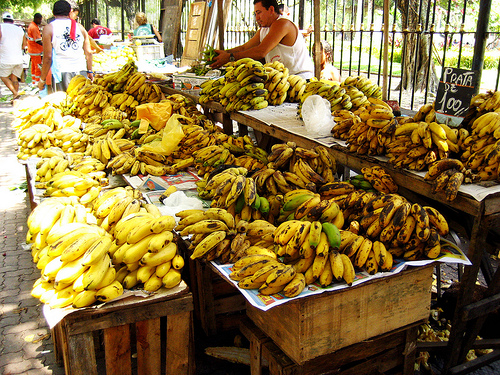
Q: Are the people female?
A: No, they are both male and female.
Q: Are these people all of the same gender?
A: No, they are both male and female.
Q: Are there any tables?
A: Yes, there is a table.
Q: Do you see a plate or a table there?
A: Yes, there is a table.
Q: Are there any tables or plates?
A: Yes, there is a table.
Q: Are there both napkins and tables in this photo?
A: No, there is a table but no napkins.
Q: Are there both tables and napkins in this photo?
A: No, there is a table but no napkins.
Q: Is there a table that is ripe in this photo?
A: Yes, there is a ripe table.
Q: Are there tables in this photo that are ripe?
A: Yes, there is a table that is ripe.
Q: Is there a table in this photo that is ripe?
A: Yes, there is a table that is ripe.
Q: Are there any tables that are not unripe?
A: Yes, there is an ripe table.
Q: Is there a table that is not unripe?
A: Yes, there is an ripe table.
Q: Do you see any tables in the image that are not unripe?
A: Yes, there is an ripe table.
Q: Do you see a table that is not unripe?
A: Yes, there is an ripe table.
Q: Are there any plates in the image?
A: No, there are no plates.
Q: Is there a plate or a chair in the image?
A: No, there are no plates or chairs.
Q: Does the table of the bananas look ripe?
A: Yes, the table is ripe.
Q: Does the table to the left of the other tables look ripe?
A: Yes, the table is ripe.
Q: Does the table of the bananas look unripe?
A: No, the table is ripe.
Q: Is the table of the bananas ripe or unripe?
A: The table is ripe.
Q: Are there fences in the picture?
A: Yes, there is a fence.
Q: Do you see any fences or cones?
A: Yes, there is a fence.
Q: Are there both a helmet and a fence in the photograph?
A: No, there is a fence but no helmets.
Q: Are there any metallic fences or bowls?
A: Yes, there is a metal fence.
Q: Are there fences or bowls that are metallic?
A: Yes, the fence is metallic.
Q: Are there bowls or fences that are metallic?
A: Yes, the fence is metallic.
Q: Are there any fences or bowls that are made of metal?
A: Yes, the fence is made of metal.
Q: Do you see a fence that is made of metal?
A: Yes, there is a fence that is made of metal.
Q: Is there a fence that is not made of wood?
A: Yes, there is a fence that is made of metal.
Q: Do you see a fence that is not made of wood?
A: Yes, there is a fence that is made of metal.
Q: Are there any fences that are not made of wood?
A: Yes, there is a fence that is made of metal.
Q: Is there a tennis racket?
A: No, there are no rackets.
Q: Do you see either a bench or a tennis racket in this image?
A: No, there are no rackets or benches.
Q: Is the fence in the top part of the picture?
A: Yes, the fence is in the top of the image.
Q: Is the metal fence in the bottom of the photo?
A: No, the fence is in the top of the image.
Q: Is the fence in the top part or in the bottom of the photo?
A: The fence is in the top of the image.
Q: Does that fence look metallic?
A: Yes, the fence is metallic.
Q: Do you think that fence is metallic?
A: Yes, the fence is metallic.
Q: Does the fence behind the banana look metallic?
A: Yes, the fence is metallic.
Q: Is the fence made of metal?
A: Yes, the fence is made of metal.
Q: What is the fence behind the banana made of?
A: The fence is made of metal.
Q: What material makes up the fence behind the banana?
A: The fence is made of metal.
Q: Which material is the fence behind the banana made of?
A: The fence is made of metal.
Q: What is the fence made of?
A: The fence is made of metal.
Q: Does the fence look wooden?
A: No, the fence is metallic.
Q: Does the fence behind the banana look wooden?
A: No, the fence is metallic.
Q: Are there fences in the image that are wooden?
A: No, there is a fence but it is metallic.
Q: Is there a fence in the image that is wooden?
A: No, there is a fence but it is metallic.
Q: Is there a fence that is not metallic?
A: No, there is a fence but it is metallic.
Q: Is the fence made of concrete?
A: No, the fence is made of metal.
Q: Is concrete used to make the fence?
A: No, the fence is made of metal.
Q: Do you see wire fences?
A: No, there is a fence but it is made of metal.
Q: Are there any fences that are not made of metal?
A: No, there is a fence but it is made of metal.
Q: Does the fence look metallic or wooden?
A: The fence is metallic.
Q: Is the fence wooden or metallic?
A: The fence is metallic.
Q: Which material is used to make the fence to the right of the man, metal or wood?
A: The fence is made of metal.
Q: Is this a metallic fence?
A: Yes, this is a metallic fence.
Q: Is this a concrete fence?
A: No, this is a metallic fence.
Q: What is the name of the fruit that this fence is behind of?
A: The fruit is a banana.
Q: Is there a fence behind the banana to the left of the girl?
A: Yes, there is a fence behind the banana.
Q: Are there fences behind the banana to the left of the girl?
A: Yes, there is a fence behind the banana.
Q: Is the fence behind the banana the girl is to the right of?
A: Yes, the fence is behind the banana.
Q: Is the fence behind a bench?
A: No, the fence is behind the banana.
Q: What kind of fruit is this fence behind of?
A: The fence is behind the banana.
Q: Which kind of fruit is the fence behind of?
A: The fence is behind the banana.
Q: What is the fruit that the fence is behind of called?
A: The fruit is a banana.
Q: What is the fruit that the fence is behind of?
A: The fruit is a banana.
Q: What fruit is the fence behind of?
A: The fence is behind the banana.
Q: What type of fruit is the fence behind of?
A: The fence is behind the banana.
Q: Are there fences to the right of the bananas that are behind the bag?
A: Yes, there is a fence to the right of the bananas.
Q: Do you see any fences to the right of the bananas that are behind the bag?
A: Yes, there is a fence to the right of the bananas.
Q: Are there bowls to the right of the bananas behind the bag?
A: No, there is a fence to the right of the bananas.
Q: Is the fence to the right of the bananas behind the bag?
A: Yes, the fence is to the right of the bananas.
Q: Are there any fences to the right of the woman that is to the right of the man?
A: Yes, there is a fence to the right of the woman.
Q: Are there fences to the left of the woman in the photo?
A: No, the fence is to the right of the woman.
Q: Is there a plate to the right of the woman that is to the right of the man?
A: No, there is a fence to the right of the woman.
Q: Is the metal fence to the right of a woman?
A: Yes, the fence is to the right of a woman.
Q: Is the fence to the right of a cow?
A: No, the fence is to the right of a woman.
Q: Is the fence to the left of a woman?
A: No, the fence is to the right of a woman.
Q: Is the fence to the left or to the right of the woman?
A: The fence is to the right of the woman.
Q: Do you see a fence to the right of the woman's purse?
A: Yes, there is a fence to the right of the purse.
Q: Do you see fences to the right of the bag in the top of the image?
A: Yes, there is a fence to the right of the purse.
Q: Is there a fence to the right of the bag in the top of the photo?
A: Yes, there is a fence to the right of the purse.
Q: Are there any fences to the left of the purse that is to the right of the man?
A: No, the fence is to the right of the purse.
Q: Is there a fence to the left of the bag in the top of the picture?
A: No, the fence is to the right of the purse.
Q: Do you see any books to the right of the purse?
A: No, there is a fence to the right of the purse.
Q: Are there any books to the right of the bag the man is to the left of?
A: No, there is a fence to the right of the purse.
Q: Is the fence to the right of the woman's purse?
A: Yes, the fence is to the right of the purse.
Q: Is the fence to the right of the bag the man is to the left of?
A: Yes, the fence is to the right of the purse.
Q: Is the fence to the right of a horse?
A: No, the fence is to the right of the purse.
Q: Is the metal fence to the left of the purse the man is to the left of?
A: No, the fence is to the right of the purse.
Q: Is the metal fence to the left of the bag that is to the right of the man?
A: No, the fence is to the right of the purse.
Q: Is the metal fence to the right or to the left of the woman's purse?
A: The fence is to the right of the purse.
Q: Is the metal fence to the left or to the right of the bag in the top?
A: The fence is to the right of the purse.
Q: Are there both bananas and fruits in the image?
A: Yes, there are both bananas and a fruit.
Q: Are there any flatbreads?
A: No, there are no flatbreads.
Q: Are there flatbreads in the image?
A: No, there are no flatbreads.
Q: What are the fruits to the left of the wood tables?
A: The fruits are bananas.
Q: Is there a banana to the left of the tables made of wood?
A: Yes, there are bananas to the left of the tables.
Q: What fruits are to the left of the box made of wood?
A: The fruits are bananas.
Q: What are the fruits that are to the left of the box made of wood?
A: The fruits are bananas.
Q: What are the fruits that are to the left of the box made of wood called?
A: The fruits are bananas.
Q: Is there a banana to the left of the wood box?
A: Yes, there are bananas to the left of the box.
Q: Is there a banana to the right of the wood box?
A: No, the bananas are to the left of the box.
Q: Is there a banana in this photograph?
A: Yes, there is a banana.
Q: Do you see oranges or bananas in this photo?
A: Yes, there is a banana.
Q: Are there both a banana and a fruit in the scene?
A: Yes, there are both a banana and a fruit.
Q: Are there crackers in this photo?
A: No, there are no crackers.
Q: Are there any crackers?
A: No, there are no crackers.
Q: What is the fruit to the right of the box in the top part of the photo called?
A: The fruit is a banana.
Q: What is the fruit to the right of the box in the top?
A: The fruit is a banana.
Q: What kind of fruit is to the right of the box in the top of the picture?
A: The fruit is a banana.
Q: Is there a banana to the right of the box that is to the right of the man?
A: Yes, there is a banana to the right of the box.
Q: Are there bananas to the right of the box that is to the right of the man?
A: Yes, there is a banana to the right of the box.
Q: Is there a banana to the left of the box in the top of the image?
A: No, the banana is to the right of the box.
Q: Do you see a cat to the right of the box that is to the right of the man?
A: No, there is a banana to the right of the box.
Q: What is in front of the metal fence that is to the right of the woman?
A: The banana is in front of the fence.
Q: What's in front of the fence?
A: The banana is in front of the fence.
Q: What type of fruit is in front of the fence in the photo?
A: The fruit is a banana.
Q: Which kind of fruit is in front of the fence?
A: The fruit is a banana.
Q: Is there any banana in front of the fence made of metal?
A: Yes, there is a banana in front of the fence.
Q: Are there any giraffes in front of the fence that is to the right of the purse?
A: No, there is a banana in front of the fence.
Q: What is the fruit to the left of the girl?
A: The fruit is a banana.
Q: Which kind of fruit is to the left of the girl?
A: The fruit is a banana.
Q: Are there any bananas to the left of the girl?
A: Yes, there is a banana to the left of the girl.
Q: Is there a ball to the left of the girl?
A: No, there is a banana to the left of the girl.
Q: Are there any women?
A: Yes, there is a woman.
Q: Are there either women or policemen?
A: Yes, there is a woman.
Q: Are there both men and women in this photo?
A: Yes, there are both a woman and a man.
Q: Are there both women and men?
A: Yes, there are both a woman and a man.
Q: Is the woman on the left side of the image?
A: Yes, the woman is on the left of the image.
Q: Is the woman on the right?
A: No, the woman is on the left of the image.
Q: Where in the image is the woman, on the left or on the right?
A: The woman is on the left of the image.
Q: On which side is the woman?
A: The woman is on the left of the image.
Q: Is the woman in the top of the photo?
A: Yes, the woman is in the top of the image.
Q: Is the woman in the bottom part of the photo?
A: No, the woman is in the top of the image.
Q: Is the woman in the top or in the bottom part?
A: The woman is in the top of the image.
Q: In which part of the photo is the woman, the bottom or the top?
A: The woman is in the top of the image.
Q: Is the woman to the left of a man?
A: No, the woman is to the right of a man.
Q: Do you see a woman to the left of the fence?
A: Yes, there is a woman to the left of the fence.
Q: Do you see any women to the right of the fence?
A: No, the woman is to the left of the fence.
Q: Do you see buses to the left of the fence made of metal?
A: No, there is a woman to the left of the fence.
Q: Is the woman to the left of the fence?
A: Yes, the woman is to the left of the fence.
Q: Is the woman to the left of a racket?
A: No, the woman is to the left of the fence.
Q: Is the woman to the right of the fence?
A: No, the woman is to the left of the fence.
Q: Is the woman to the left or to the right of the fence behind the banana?
A: The woman is to the left of the fence.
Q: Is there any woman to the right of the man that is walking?
A: Yes, there is a woman to the right of the man.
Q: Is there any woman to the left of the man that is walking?
A: No, the woman is to the right of the man.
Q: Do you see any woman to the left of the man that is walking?
A: No, the woman is to the right of the man.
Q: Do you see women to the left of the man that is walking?
A: No, the woman is to the right of the man.